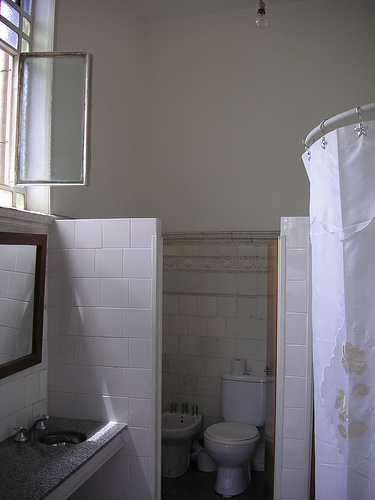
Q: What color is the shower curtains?
A: White.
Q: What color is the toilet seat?
A: White.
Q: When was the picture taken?
A: Daytime.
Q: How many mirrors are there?
A: One.